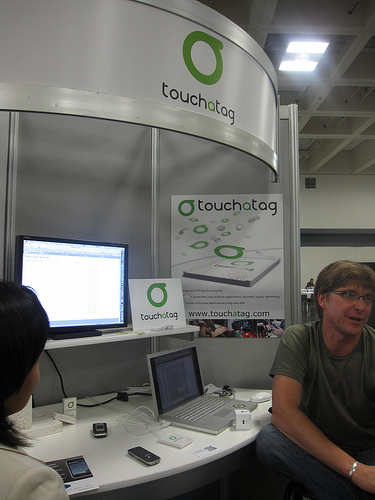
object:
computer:
[12, 232, 130, 341]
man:
[254, 257, 375, 499]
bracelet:
[348, 460, 359, 480]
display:
[0, 3, 281, 500]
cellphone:
[92, 422, 108, 438]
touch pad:
[157, 430, 193, 450]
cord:
[115, 405, 171, 437]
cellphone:
[127, 444, 161, 467]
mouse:
[249, 390, 273, 403]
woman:
[0, 278, 71, 498]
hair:
[0, 279, 52, 453]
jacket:
[0, 444, 70, 500]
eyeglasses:
[331, 287, 375, 303]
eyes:
[345, 289, 355, 297]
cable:
[116, 405, 172, 438]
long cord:
[44, 348, 153, 409]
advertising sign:
[171, 192, 285, 319]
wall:
[0, 0, 303, 410]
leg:
[254, 423, 375, 499]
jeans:
[253, 423, 375, 500]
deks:
[17, 388, 275, 499]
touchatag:
[161, 81, 236, 126]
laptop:
[146, 341, 260, 435]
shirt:
[267, 318, 374, 461]